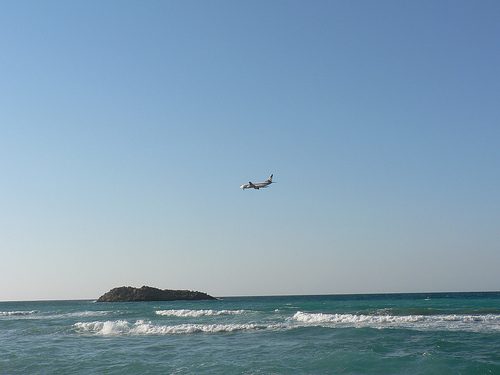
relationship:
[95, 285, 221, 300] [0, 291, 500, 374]
island next to ocean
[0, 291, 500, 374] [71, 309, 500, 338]
ocean has wave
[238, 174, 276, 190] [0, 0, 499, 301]
plane in sky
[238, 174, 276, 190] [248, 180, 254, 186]
plane has wing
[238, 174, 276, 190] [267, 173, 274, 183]
plane has tail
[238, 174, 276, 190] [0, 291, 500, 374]
plane flying over ocean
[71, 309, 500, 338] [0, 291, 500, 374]
wave in ocean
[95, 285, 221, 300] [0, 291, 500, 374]
island in ocean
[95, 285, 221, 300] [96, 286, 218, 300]
island has trees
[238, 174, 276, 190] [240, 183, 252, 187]
plane has nose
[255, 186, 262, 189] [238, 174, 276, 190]
wheel under plane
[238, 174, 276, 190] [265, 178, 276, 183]
plane has wing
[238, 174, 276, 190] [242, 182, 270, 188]
plane has body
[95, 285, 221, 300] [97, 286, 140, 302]
island has edge